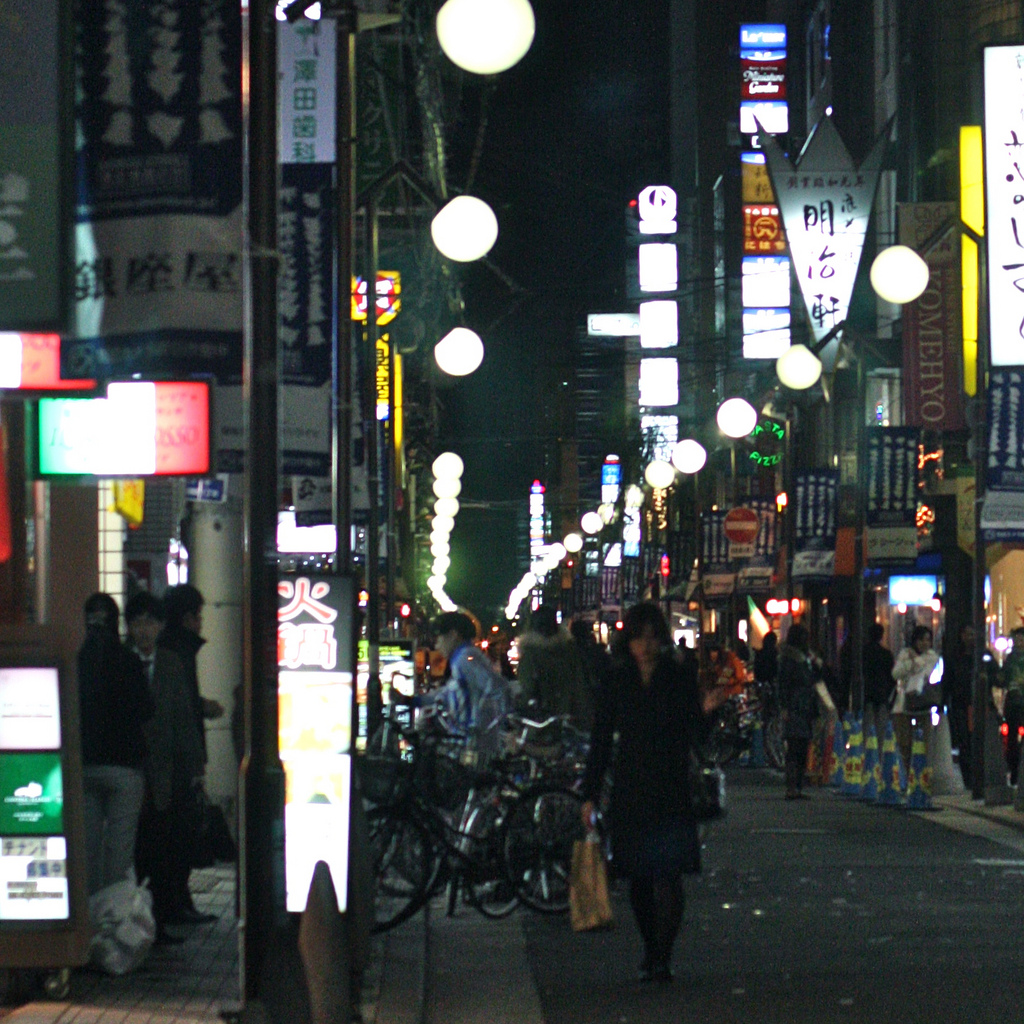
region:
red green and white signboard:
[33, 377, 215, 479]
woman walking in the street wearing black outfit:
[578, 597, 727, 989]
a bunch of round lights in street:
[417, 13, 940, 602]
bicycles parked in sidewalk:
[354, 702, 595, 934]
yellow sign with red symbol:
[344, 265, 418, 341]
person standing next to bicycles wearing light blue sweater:
[429, 614, 513, 752]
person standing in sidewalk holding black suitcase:
[137, 581, 223, 926]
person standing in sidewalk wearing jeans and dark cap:
[66, 574, 149, 903]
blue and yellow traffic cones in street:
[827, 708, 938, 820]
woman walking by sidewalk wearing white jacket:
[894, 622, 946, 720]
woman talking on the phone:
[579, 594, 731, 975]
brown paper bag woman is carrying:
[563, 806, 620, 936]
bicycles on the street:
[354, 676, 617, 936]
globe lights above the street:
[407, 7, 936, 646]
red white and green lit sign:
[31, 367, 206, 481]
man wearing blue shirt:
[423, 610, 542, 778]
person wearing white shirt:
[892, 617, 969, 799]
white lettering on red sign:
[913, 264, 968, 432]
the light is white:
[411, 0, 549, 99]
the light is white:
[414, 186, 507, 275]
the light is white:
[420, 315, 501, 392]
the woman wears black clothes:
[559, 586, 738, 1014]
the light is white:
[765, 333, 838, 403]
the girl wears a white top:
[878, 612, 948, 808]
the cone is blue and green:
[891, 713, 945, 822]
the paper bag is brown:
[553, 818, 623, 948]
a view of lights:
[420, 167, 531, 300]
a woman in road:
[584, 619, 799, 956]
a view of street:
[403, 470, 1023, 990]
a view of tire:
[369, 796, 490, 929]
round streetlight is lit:
[426, 195, 498, 262]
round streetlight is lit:
[432, 2, 537, 74]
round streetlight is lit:
[432, 326, 483, 375]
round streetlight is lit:
[430, 450, 466, 483]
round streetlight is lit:
[430, 472, 463, 494]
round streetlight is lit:
[864, 245, 929, 308]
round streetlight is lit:
[774, 337, 823, 393]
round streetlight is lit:
[718, 398, 758, 436]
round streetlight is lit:
[671, 436, 709, 476]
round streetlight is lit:
[644, 456, 677, 492]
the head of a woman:
[621, 599, 675, 667]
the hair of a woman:
[617, 599, 662, 629]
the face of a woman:
[631, 621, 666, 659]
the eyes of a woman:
[618, 624, 664, 651]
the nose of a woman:
[643, 633, 660, 654]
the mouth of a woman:
[636, 647, 649, 660]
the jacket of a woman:
[574, 654, 708, 888]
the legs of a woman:
[610, 840, 706, 970]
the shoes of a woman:
[623, 948, 691, 996]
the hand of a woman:
[570, 783, 621, 842]